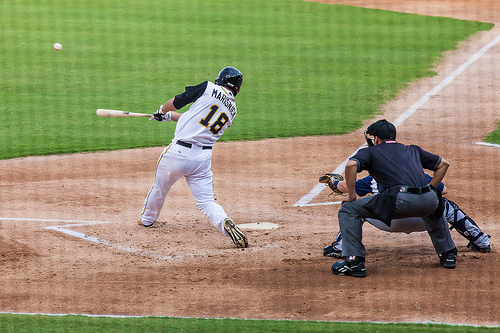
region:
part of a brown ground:
[251, 247, 311, 299]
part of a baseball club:
[94, 91, 135, 130]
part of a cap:
[372, 120, 396, 139]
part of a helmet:
[216, 69, 237, 89]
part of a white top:
[183, 121, 198, 138]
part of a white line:
[288, 155, 322, 216]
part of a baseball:
[35, 33, 83, 57]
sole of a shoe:
[229, 225, 249, 252]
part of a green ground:
[24, 81, 80, 115]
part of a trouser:
[403, 200, 425, 228]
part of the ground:
[261, 275, 308, 312]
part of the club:
[101, 97, 138, 133]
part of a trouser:
[399, 206, 436, 227]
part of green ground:
[279, 72, 325, 147]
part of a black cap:
[363, 110, 392, 144]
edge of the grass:
[278, 126, 315, 141]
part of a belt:
[177, 133, 192, 153]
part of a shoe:
[322, 242, 372, 279]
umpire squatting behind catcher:
[329, 118, 461, 276]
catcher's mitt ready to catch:
[307, 166, 365, 198]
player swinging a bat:
[95, 60, 253, 257]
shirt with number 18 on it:
[198, 97, 233, 136]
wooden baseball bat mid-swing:
[99, 106, 169, 136]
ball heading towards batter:
[46, 33, 64, 54]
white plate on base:
[227, 212, 282, 243]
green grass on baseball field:
[265, 17, 362, 104]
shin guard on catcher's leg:
[442, 195, 494, 258]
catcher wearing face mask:
[361, 123, 393, 147]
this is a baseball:
[48, 36, 73, 61]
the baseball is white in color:
[51, 42, 62, 48]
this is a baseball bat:
[93, 107, 164, 119]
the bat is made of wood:
[96, 109, 151, 119]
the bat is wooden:
[95, 108, 146, 117]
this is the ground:
[34, 171, 82, 216]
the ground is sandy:
[76, 221, 167, 285]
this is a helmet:
[223, 70, 235, 87]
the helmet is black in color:
[222, 70, 239, 80]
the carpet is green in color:
[113, 16, 199, 63]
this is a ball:
[45, 31, 75, 63]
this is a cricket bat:
[89, 96, 149, 123]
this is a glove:
[314, 162, 339, 199]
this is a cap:
[366, 115, 397, 142]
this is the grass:
[209, 0, 361, 97]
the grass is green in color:
[294, 48, 337, 106]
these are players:
[107, 60, 472, 296]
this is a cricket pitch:
[0, 32, 491, 327]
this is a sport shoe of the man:
[326, 252, 375, 284]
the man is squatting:
[323, 114, 465, 276]